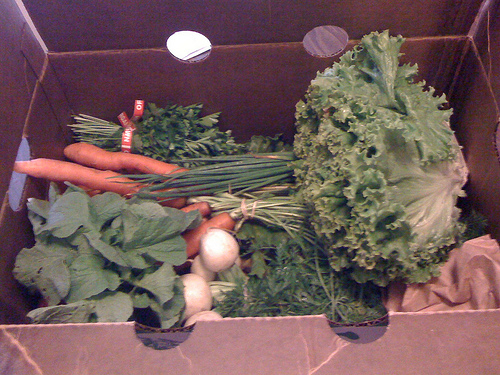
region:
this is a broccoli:
[308, 50, 438, 263]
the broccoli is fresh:
[300, 41, 452, 270]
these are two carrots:
[45, 145, 135, 180]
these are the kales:
[12, 202, 181, 310]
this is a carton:
[176, 19, 283, 90]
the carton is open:
[169, 0, 301, 87]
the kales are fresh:
[23, 197, 176, 300]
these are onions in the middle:
[211, 150, 278, 186]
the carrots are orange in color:
[49, 139, 120, 182]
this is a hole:
[161, 22, 218, 64]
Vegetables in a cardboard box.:
[0, 0, 497, 373]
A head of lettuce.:
[292, 29, 466, 286]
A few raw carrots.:
[12, 140, 192, 205]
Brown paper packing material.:
[385, 234, 498, 311]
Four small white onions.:
[182, 228, 239, 318]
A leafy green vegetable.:
[11, 180, 191, 326]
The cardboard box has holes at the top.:
[163, 23, 348, 63]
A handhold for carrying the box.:
[5, 134, 31, 214]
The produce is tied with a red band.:
[67, 98, 219, 153]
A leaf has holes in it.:
[11, 243, 72, 308]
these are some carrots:
[28, 153, 168, 179]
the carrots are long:
[22, 147, 149, 191]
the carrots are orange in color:
[36, 160, 128, 172]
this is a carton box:
[226, 46, 270, 96]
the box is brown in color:
[233, 46, 278, 117]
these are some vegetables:
[316, 66, 411, 224]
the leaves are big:
[287, 198, 389, 273]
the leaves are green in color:
[337, 200, 402, 255]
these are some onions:
[182, 231, 227, 320]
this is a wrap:
[116, 115, 139, 155]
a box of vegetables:
[35, 26, 494, 359]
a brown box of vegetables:
[8, 18, 485, 373]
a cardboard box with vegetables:
[29, 28, 496, 363]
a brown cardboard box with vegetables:
[4, 33, 499, 352]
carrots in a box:
[29, 77, 356, 287]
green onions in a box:
[93, 111, 429, 335]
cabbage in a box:
[272, 1, 494, 258]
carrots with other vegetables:
[52, 98, 329, 290]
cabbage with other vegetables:
[197, 34, 496, 333]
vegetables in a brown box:
[21, 11, 485, 342]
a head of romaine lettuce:
[296, 50, 454, 287]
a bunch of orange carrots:
[41, 126, 228, 241]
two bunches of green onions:
[185, 151, 314, 233]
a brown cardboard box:
[69, 340, 439, 368]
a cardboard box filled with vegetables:
[41, 64, 478, 358]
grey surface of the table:
[3, 176, 28, 203]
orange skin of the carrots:
[48, 145, 158, 195]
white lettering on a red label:
[118, 113, 134, 149]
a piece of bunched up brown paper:
[401, 251, 494, 314]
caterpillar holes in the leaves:
[28, 260, 64, 295]